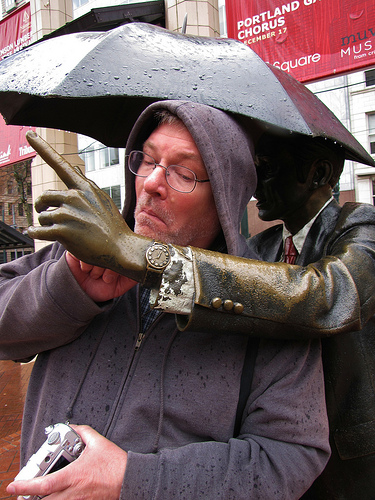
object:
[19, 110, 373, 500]
statue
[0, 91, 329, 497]
man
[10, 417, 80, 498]
camera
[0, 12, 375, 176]
umbrella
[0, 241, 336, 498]
sweatshirt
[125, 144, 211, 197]
glasses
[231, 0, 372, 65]
sign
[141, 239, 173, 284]
watch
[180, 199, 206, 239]
skin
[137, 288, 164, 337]
shirt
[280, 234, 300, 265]
tie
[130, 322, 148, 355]
zipper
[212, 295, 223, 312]
buttons